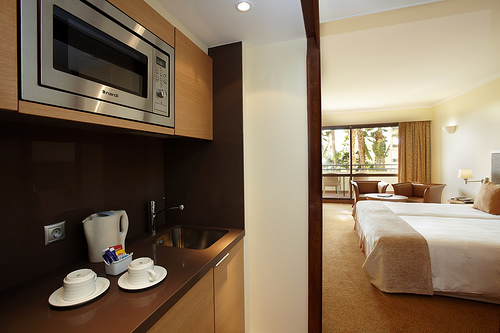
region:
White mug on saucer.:
[131, 261, 143, 272]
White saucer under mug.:
[124, 273, 179, 292]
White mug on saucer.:
[58, 273, 114, 300]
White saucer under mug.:
[53, 275, 123, 322]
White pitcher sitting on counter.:
[86, 213, 143, 258]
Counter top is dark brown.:
[24, 305, 96, 331]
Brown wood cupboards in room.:
[205, 292, 247, 331]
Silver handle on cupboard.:
[213, 250, 233, 263]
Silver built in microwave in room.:
[19, 23, 209, 109]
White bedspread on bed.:
[428, 213, 482, 285]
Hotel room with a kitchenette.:
[0, 0, 496, 330]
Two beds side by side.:
[351, 152, 497, 293]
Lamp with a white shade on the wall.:
[451, 161, 486, 186]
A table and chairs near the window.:
[352, 170, 429, 201]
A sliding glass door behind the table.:
[320, 122, 426, 202]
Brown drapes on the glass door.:
[397, 120, 427, 193]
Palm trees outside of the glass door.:
[321, 127, 396, 172]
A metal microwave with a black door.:
[15, 46, 175, 126]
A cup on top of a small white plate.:
[115, 256, 165, 289]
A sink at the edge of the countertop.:
[140, 197, 238, 254]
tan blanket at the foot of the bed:
[359, 193, 437, 310]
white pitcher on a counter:
[73, 184, 131, 261]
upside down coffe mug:
[57, 262, 104, 309]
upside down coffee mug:
[129, 253, 155, 286]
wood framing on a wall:
[301, 4, 339, 329]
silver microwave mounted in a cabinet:
[27, 9, 185, 129]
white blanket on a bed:
[403, 203, 499, 275]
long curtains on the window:
[397, 120, 435, 195]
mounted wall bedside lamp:
[453, 165, 492, 195]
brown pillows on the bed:
[470, 170, 497, 231]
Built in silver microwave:
[20, 0, 179, 129]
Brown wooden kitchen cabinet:
[173, 27, 218, 142]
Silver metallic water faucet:
[141, 186, 188, 237]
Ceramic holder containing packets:
[100, 245, 132, 273]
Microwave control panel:
[148, 50, 173, 115]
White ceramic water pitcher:
[73, 207, 136, 264]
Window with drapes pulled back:
[320, 122, 434, 202]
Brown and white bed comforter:
[351, 190, 498, 293]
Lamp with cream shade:
[453, 165, 474, 197]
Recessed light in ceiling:
[232, 1, 256, 13]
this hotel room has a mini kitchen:
[6, 0, 239, 331]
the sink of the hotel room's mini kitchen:
[138, 191, 233, 259]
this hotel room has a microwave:
[3, 3, 190, 135]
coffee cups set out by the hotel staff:
[47, 253, 164, 310]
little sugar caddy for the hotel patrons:
[98, 245, 135, 275]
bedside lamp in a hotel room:
[455, 164, 494, 189]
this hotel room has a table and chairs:
[347, 175, 445, 205]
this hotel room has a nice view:
[322, 118, 399, 182]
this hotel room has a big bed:
[352, 175, 497, 300]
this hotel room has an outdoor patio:
[321, 120, 401, 200]